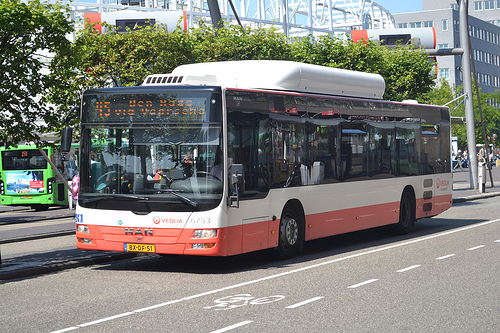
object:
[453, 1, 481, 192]
metal pole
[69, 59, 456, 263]
bus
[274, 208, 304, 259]
bus wheel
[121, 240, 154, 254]
license plate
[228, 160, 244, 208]
mirror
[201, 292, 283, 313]
bike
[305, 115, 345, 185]
window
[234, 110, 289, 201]
window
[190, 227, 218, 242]
light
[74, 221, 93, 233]
light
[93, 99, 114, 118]
number 45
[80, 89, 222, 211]
windshield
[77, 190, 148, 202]
wiper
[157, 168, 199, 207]
wiper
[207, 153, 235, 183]
driver